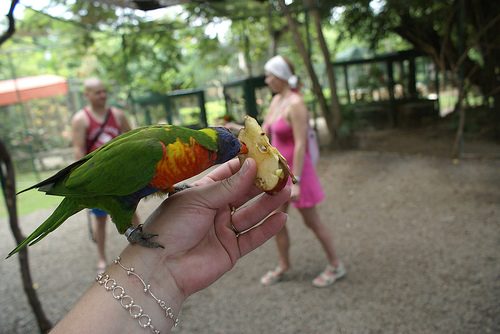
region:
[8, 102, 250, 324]
a bird sitting on a person's hand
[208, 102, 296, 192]
a bird eating a apple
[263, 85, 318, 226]
a woman wearing a pink dress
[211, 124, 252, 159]
a bird with a orange beak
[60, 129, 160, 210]
a bird with green feathers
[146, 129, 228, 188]
a bird with yellow and orange feathers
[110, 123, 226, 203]
green and orange bird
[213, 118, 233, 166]
bird has blue head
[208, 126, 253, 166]
bird has orange beak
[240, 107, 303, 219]
bird is eating fruit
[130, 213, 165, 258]
bird has black talons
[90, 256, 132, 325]
woman has two bracelets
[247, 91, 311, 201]
woman has pink dress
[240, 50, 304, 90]
woman has white headband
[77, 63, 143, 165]
man has red shirt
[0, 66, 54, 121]
orange canopy behind man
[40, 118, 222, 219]
green bird on hand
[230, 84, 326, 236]
bird is eating fruit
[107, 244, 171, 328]
two bracelets on wrist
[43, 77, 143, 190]
man has red shirt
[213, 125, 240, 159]
bird's head is blue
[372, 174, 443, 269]
ground is light brown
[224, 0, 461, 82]
green trees in distance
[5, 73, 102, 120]
orange canopy behind man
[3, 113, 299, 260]
parrot bending head to eat apple slice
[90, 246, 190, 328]
thin silver bracelets on wrist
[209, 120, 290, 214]
thumb on top of apple slice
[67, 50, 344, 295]
man and woman facing each other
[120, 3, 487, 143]
trees over boxy open structures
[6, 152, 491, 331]
gray gravel covering ground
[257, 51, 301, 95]
white and wide headband on woman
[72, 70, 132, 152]
man in red and white tank top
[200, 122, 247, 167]
bird with yellow, blue and red head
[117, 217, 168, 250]
metal band on top of black toes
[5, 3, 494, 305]
a scene during the day time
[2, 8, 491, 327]
an image outside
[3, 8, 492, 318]
a scene at a park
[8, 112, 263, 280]
a colorful parrot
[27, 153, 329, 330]
a white person's hand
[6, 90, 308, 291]
a bird eating a fruit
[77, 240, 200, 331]
a white bracelet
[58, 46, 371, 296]
a couple of people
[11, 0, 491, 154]
a row of green trees in the background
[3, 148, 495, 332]
a rocky gray floor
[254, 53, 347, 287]
woman in pink sun dress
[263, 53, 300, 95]
white cover on head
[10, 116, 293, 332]
parrot standing on wrist and hand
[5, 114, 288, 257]
parrot eating from slice of apple